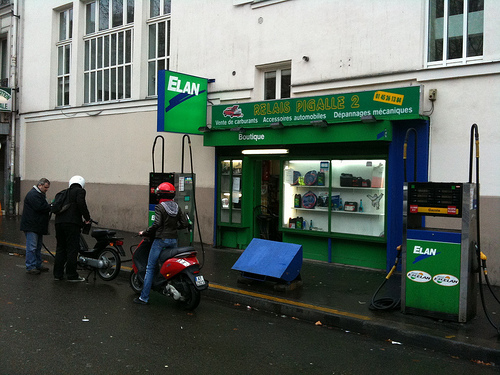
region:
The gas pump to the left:
[131, 132, 196, 248]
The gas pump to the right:
[381, 172, 490, 328]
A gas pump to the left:
[138, 163, 201, 268]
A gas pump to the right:
[370, 177, 480, 327]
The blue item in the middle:
[230, 232, 303, 292]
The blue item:
[228, 229, 303, 287]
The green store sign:
[154, 69, 209, 139]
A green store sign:
[149, 66, 212, 133]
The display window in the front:
[279, 160, 385, 248]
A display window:
[286, 156, 386, 247]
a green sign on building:
[166, 67, 218, 144]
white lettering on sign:
[167, 76, 201, 101]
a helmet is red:
[153, 182, 175, 200]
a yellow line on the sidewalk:
[201, 277, 392, 324]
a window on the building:
[53, 54, 76, 100]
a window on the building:
[84, 55, 131, 108]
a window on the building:
[149, 53, 175, 95]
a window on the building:
[261, 62, 281, 102]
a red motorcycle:
[136, 235, 206, 317]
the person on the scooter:
[128, 180, 208, 313]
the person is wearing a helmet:
[134, 181, 188, 305]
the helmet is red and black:
[154, 181, 177, 201]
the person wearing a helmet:
[54, 173, 91, 283]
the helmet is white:
[69, 175, 85, 185]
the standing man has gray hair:
[21, 176, 52, 271]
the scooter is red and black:
[131, 228, 206, 305]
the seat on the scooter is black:
[128, 226, 208, 310]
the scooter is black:
[76, 218, 126, 282]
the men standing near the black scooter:
[19, 178, 126, 282]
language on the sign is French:
[209, 85, 423, 130]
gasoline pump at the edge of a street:
[365, 123, 496, 324]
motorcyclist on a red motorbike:
[128, 180, 209, 312]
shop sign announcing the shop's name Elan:
[154, 66, 213, 138]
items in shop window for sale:
[279, 153, 391, 241]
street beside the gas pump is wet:
[0, 248, 499, 373]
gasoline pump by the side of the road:
[145, 131, 206, 273]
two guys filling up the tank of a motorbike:
[16, 173, 127, 286]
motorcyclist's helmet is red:
[153, 179, 178, 202]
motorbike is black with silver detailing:
[72, 227, 128, 284]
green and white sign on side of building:
[150, 66, 217, 138]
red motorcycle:
[124, 224, 211, 313]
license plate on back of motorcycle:
[190, 272, 210, 289]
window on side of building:
[260, 66, 296, 101]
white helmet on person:
[63, 171, 87, 191]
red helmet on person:
[150, 179, 180, 198]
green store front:
[207, 81, 425, 278]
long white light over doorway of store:
[236, 145, 291, 159]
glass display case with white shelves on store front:
[278, 155, 389, 243]